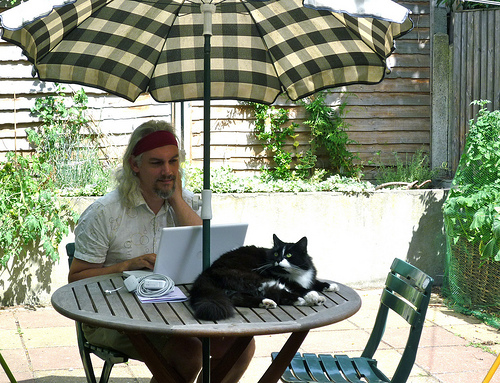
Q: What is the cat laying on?
A: A table.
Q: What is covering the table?
A: An umbrella.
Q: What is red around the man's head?
A: A headband.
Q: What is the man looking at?
A: A laptop.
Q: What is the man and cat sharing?
A: An outdoor table.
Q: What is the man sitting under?
A: An umbrella.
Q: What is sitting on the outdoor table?
A: A cat.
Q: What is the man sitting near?
A: A cat.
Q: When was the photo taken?
A: In the daytime.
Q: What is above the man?
A: Umbrella.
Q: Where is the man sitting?
A: Patio.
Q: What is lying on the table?
A: Cat.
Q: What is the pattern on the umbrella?
A: Checkered.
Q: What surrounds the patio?
A: Plants and fence.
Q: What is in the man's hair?
A: Headband.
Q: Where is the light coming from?
A: Sun.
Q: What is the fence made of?
A: Wood.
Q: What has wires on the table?
A: Charger.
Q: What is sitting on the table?
A: A cat.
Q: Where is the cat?
A: On the table.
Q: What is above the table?
A: An umbrella.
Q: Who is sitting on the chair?
A: A man using a computer.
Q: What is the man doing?
A: Using a computer.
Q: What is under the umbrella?
A: A table.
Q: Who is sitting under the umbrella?
A: A man using a computer.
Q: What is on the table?
A: A computer and a cat.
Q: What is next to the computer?
A: A cat.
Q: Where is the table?
A: On a patio.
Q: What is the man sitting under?
A: Umbrella.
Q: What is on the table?
A: Cat.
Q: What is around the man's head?
A: Band.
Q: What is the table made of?
A: Plastic.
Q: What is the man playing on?
A: Computer.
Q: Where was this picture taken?
A: Patio.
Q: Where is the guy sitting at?
A: Outside at a table.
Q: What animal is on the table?
A: A cat.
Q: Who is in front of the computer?
A: A man.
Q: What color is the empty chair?
A: Green.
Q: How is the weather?
A: Sunny.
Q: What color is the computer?
A: White.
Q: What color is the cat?
A: Black and white.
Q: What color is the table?
A: Grey or silver.